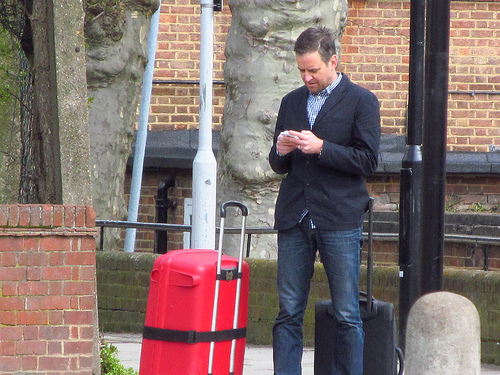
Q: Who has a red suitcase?
A: Man.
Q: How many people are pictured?
A: 1.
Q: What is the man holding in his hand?
A: Phone.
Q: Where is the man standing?
A: Sidewalk.